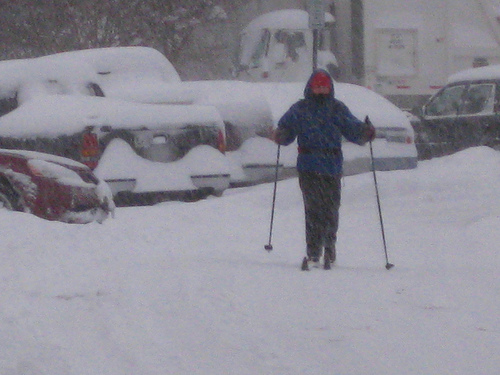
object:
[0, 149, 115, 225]
hood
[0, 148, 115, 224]
sedan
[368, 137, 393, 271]
ski pole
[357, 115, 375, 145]
hand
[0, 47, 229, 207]
truck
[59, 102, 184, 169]
rear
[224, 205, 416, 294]
skiis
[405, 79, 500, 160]
sedan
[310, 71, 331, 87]
cap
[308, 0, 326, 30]
sign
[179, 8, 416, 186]
truck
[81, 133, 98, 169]
light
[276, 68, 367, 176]
jacket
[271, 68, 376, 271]
person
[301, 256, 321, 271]
skis